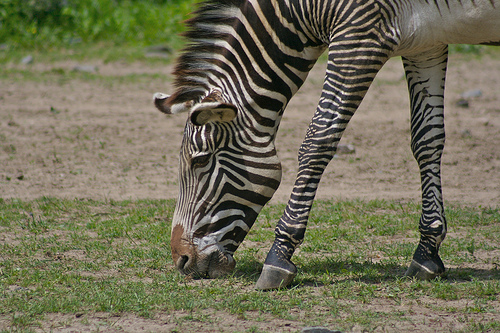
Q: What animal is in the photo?
A: Zebra.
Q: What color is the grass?
A: Green.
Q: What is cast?
A: Shadow.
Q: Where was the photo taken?
A: Park.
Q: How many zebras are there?
A: One.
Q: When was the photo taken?
A: Daytime.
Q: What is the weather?
A: Sunny.